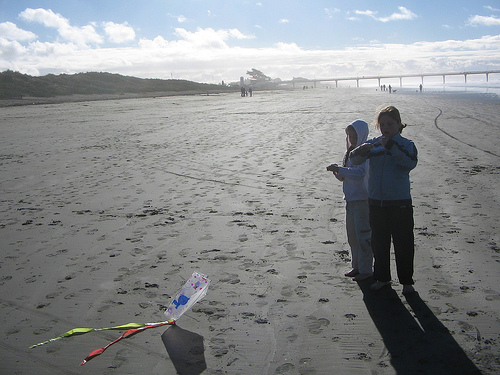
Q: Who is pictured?
A: A young man and young woman.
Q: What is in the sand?
A: A kite.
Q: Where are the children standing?
A: On the beach.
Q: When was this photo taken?
A: On a trip to the beach on a nice day.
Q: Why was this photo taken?
A: To show the beach and kids.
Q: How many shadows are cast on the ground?
A: 3.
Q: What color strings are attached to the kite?
A: Red and yellow.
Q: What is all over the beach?
A: Footprints.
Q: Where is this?
A: On a beach.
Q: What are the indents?
A: Footprints.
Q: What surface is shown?
A: Sand.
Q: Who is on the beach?
A: Two young girls.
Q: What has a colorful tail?
A: A kite, lying on the beach.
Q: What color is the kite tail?
A: Green, pink and orange.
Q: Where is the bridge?
A: In the far distance.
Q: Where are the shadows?
A: Under the kite and the girls.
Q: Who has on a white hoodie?
A: The shorter of two girls on a beach.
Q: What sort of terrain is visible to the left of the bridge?
A: Hillsides.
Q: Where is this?
A: The beach.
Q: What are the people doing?
A: Flying a kite.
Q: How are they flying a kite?
A: With a string.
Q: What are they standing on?
A: Sand.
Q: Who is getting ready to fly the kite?
A: Two people.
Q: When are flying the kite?
A: During the day.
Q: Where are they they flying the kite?
A: On the beach.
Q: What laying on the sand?
A: A kite.